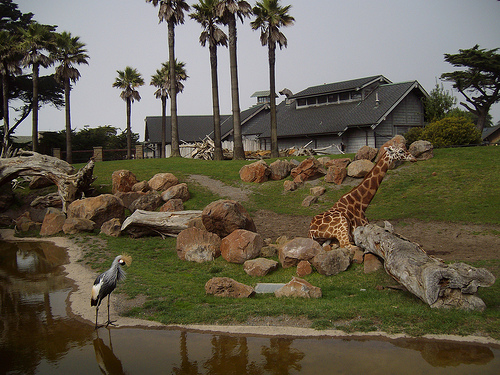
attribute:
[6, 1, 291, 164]
trees — green, tall, very tall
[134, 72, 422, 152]
building — white, big, wide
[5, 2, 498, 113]
sky — blue, purple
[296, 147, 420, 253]
giraffe — sitting, tall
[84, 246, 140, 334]
bird — grey, small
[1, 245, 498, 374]
water — brown, dirty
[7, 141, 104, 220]
log — large, brown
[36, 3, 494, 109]
sky — blue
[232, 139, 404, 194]
boulders — orange, brown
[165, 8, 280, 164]
trees — tall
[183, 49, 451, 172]
roof — dark gray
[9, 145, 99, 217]
tree — big, rotten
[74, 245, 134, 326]
bird — tall, black, wite, grey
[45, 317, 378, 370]
water — brown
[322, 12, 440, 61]
sky — grey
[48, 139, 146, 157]
stone posts — large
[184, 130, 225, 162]
pile — large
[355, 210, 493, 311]
log — large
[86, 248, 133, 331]
bird — standing